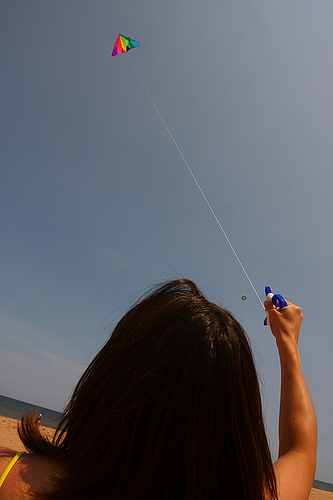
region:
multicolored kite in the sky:
[110, 32, 139, 62]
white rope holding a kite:
[122, 44, 269, 325]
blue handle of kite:
[261, 277, 290, 326]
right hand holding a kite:
[263, 288, 307, 349]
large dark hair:
[17, 276, 273, 498]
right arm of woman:
[261, 294, 316, 499]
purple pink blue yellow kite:
[111, 32, 139, 66]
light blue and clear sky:
[1, 1, 331, 478]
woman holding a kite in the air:
[0, 277, 320, 497]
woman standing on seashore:
[0, 273, 318, 498]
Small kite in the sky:
[110, 27, 146, 55]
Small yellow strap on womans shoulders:
[0, 445, 24, 496]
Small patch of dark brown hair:
[219, 303, 282, 498]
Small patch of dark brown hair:
[184, 280, 212, 498]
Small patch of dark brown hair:
[162, 281, 192, 499]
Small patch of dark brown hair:
[119, 297, 161, 496]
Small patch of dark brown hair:
[94, 344, 136, 499]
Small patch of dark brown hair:
[55, 383, 104, 498]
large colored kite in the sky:
[107, 29, 141, 63]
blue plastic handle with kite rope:
[255, 282, 288, 328]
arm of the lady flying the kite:
[244, 286, 316, 499]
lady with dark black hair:
[1, 265, 321, 499]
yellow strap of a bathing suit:
[0, 444, 27, 486]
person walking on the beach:
[34, 408, 43, 427]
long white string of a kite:
[125, 51, 270, 313]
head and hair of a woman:
[10, 274, 278, 499]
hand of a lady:
[256, 289, 310, 343]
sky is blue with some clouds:
[1, 1, 332, 475]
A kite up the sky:
[104, 5, 144, 72]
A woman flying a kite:
[22, 249, 257, 489]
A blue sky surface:
[11, 272, 78, 366]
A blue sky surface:
[18, 223, 116, 301]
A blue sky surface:
[14, 97, 149, 169]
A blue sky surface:
[18, 22, 150, 89]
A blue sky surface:
[171, 11, 315, 112]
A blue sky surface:
[218, 134, 308, 230]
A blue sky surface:
[130, 208, 188, 268]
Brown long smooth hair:
[102, 333, 218, 461]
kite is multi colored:
[97, 24, 152, 60]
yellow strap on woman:
[7, 434, 34, 495]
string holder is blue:
[261, 274, 298, 339]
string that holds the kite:
[126, 50, 280, 333]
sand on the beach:
[0, 418, 56, 456]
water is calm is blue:
[4, 374, 96, 441]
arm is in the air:
[191, 260, 331, 498]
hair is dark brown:
[12, 404, 249, 496]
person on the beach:
[18, 404, 51, 435]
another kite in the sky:
[213, 268, 254, 325]